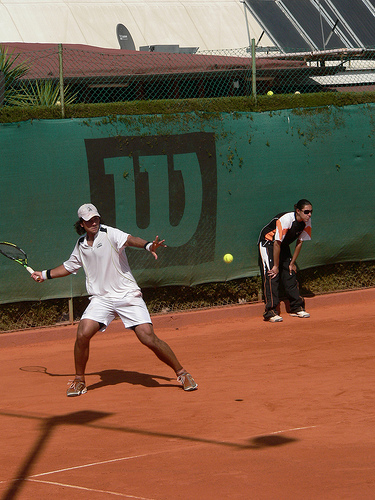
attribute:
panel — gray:
[225, 3, 375, 56]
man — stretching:
[3, 191, 212, 410]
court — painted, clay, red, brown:
[6, 310, 372, 499]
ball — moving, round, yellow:
[215, 250, 238, 265]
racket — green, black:
[1, 236, 45, 285]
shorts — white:
[70, 292, 163, 336]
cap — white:
[71, 201, 102, 223]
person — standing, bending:
[243, 180, 340, 329]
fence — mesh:
[0, 39, 372, 301]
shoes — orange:
[56, 369, 202, 399]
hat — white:
[73, 203, 105, 224]